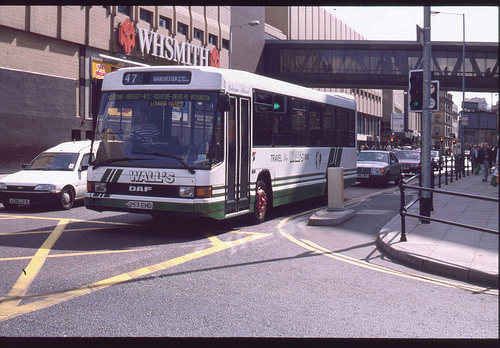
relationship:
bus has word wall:
[71, 56, 373, 234] [125, 164, 179, 186]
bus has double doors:
[71, 56, 373, 234] [219, 88, 256, 221]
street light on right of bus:
[407, 67, 425, 111] [255, 6, 491, 250]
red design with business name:
[114, 11, 141, 60] [133, 22, 214, 71]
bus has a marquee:
[71, 56, 373, 234] [116, 64, 195, 90]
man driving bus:
[120, 99, 166, 160] [71, 56, 373, 234]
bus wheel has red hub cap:
[254, 174, 274, 227] [252, 187, 271, 217]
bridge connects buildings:
[254, 30, 498, 93] [1, 6, 382, 80]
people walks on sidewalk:
[464, 137, 499, 183] [374, 147, 499, 293]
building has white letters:
[6, 6, 371, 130] [133, 22, 214, 71]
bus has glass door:
[71, 56, 373, 234] [219, 88, 256, 221]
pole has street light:
[417, 4, 440, 224] [407, 67, 425, 111]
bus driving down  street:
[71, 56, 373, 234] [6, 178, 301, 348]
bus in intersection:
[71, 56, 373, 234] [3, 194, 391, 347]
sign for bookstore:
[133, 22, 214, 71] [6, 3, 227, 113]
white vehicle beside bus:
[0, 130, 100, 214] [71, 56, 373, 234]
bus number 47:
[71, 56, 373, 234] [118, 64, 143, 92]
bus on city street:
[71, 56, 373, 234] [5, 154, 499, 332]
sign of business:
[108, 12, 231, 70] [1, 3, 312, 179]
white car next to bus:
[0, 130, 100, 214] [71, 56, 373, 234]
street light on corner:
[407, 67, 425, 111] [365, 99, 499, 322]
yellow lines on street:
[0, 206, 274, 332] [5, 154, 499, 332]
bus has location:
[71, 56, 373, 234] [116, 64, 195, 90]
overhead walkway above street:
[254, 30, 498, 93] [5, 154, 499, 332]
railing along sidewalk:
[384, 146, 498, 250] [374, 147, 499, 293]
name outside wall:
[133, 22, 214, 71] [6, 6, 371, 130]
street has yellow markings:
[5, 154, 499, 332] [6, 178, 301, 348]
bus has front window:
[71, 56, 373, 234] [85, 84, 226, 174]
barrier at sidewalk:
[366, 126, 472, 295] [374, 147, 499, 293]